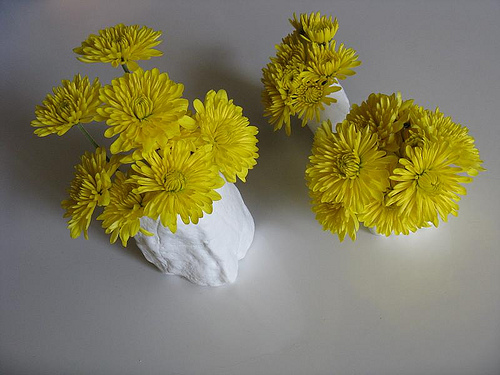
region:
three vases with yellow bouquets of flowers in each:
[31, 9, 481, 289]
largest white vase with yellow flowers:
[26, 22, 258, 291]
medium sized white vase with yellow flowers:
[305, 90, 484, 240]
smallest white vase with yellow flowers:
[255, 5, 359, 137]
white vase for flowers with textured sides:
[124, 182, 255, 288]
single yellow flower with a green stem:
[72, 20, 158, 66]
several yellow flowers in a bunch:
[302, 92, 477, 232]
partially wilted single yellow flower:
[286, 10, 336, 41]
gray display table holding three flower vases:
[0, 0, 485, 361]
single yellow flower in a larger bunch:
[28, 75, 95, 140]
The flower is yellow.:
[123, 138, 224, 231]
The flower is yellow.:
[94, 63, 189, 156]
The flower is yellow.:
[175, 87, 265, 190]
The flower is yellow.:
[28, 62, 109, 154]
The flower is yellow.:
[73, 15, 167, 75]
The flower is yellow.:
[306, 117, 391, 212]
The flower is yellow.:
[380, 140, 463, 222]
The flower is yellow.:
[98, 170, 160, 250]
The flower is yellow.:
[291, 8, 347, 53]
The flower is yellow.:
[341, 83, 411, 156]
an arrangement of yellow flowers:
[33, 15, 260, 239]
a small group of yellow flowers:
[261, 12, 481, 242]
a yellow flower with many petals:
[398, 143, 464, 225]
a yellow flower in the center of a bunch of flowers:
[96, 66, 191, 145]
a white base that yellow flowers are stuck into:
[133, 159, 255, 285]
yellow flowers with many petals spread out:
[304, 90, 484, 235]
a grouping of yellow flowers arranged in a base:
[41, 24, 260, 249]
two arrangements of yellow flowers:
[50, 9, 481, 284]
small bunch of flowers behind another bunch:
[260, 5, 362, 133]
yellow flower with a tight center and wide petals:
[397, 147, 464, 218]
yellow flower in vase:
[289, 31, 451, 208]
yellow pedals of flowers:
[315, 128, 376, 208]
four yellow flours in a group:
[303, 103, 465, 222]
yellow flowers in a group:
[261, 2, 357, 119]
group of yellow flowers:
[42, 32, 237, 227]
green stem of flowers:
[60, 120, 105, 143]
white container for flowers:
[132, 205, 251, 291]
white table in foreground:
[206, 254, 434, 354]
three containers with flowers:
[17, 0, 446, 285]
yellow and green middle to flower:
[131, 96, 151, 118]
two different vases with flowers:
[53, 34, 418, 320]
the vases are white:
[46, 8, 461, 302]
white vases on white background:
[46, 8, 435, 270]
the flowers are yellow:
[68, 8, 414, 239]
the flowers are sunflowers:
[65, 20, 435, 261]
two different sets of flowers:
[61, 26, 460, 303]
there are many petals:
[102, 29, 446, 286]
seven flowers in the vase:
[11, 1, 261, 261]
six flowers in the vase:
[304, 80, 486, 270]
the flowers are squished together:
[249, 9, 383, 154]